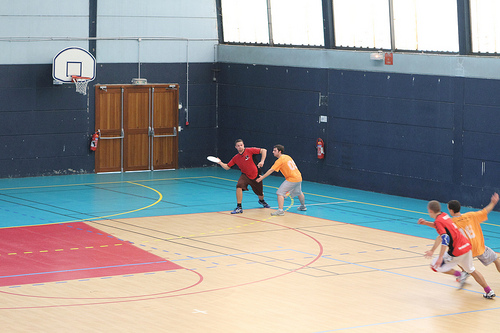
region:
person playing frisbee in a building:
[201, 133, 276, 213]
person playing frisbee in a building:
[249, 138, 306, 215]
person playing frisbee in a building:
[417, 198, 497, 302]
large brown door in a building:
[88, 80, 183, 176]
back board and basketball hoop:
[48, 45, 99, 94]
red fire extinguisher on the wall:
[312, 132, 327, 161]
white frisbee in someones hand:
[202, 151, 222, 164]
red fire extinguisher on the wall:
[86, 128, 103, 157]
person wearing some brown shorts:
[202, 136, 272, 217]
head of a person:
[230, 139, 245, 150]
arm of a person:
[215, 151, 236, 171]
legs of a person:
[226, 182, 273, 209]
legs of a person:
[274, 180, 311, 215]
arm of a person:
[255, 160, 280, 181]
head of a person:
[420, 202, 445, 219]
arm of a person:
[436, 223, 453, 265]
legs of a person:
[443, 256, 497, 302]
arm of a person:
[476, 190, 498, 222]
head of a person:
[448, 199, 470, 214]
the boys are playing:
[185, 121, 336, 231]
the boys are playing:
[401, 191, 487, 281]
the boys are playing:
[383, 172, 488, 328]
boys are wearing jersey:
[221, 138, 307, 208]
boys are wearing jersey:
[410, 180, 496, 316]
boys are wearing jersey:
[185, 115, 306, 231]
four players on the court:
[202, 128, 499, 303]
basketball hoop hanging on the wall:
[49, 42, 96, 99]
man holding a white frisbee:
[207, 133, 275, 215]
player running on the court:
[410, 190, 493, 307]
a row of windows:
[218, 0, 498, 54]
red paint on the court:
[1, 220, 179, 294]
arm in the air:
[482, 190, 499, 220]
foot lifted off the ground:
[433, 259, 469, 284]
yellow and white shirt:
[268, 155, 304, 183]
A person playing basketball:
[264, 153, 318, 230]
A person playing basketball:
[201, 133, 269, 215]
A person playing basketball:
[405, 207, 490, 305]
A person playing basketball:
[450, 191, 498, 239]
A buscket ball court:
[28, 164, 162, 284]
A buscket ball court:
[315, 161, 377, 253]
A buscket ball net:
[61, 68, 103, 99]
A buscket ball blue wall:
[325, 63, 435, 177]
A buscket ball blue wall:
[208, 65, 290, 139]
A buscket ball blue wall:
[10, 67, 58, 182]